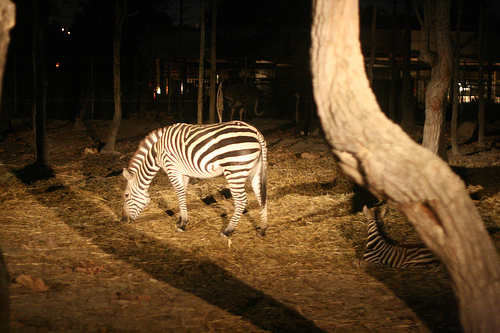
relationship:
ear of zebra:
[121, 165, 133, 181] [120, 120, 268, 236]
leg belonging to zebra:
[160, 164, 188, 230] [120, 120, 268, 236]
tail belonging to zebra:
[255, 138, 268, 209] [95, 110, 281, 244]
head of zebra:
[121, 167, 150, 222] [120, 120, 268, 236]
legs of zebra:
[162, 170, 271, 238] [115, 115, 274, 237]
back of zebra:
[218, 169, 249, 238] [81, 111, 323, 223]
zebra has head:
[122, 130, 273, 230] [112, 159, 152, 226]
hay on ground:
[67, 243, 117, 280] [48, 242, 377, 319]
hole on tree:
[416, 200, 452, 242] [310, 0, 499, 332]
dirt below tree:
[30, 170, 370, 237] [310, 0, 499, 332]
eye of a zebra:
[124, 193, 129, 197] [362, 203, 454, 281]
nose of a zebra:
[122, 206, 144, 231] [97, 97, 295, 238]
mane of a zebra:
[124, 131, 176, 180] [120, 120, 268, 236]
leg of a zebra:
[164, 167, 190, 233] [120, 120, 268, 236]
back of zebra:
[218, 169, 249, 238] [115, 115, 274, 237]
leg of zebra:
[164, 167, 190, 233] [120, 120, 268, 236]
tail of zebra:
[236, 120, 274, 213] [81, 112, 301, 252]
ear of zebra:
[122, 167, 132, 180] [120, 120, 268, 236]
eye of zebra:
[119, 183, 132, 205] [95, 110, 281, 244]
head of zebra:
[122, 180, 150, 223] [120, 120, 268, 236]